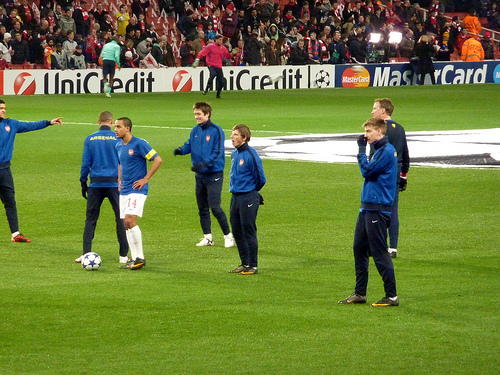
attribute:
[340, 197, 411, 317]
pants — blue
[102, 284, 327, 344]
lawn — pictured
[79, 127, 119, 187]
jacket — blue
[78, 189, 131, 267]
pants — black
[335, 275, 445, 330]
shoes — red 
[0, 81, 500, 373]
field — green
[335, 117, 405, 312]
player — soccer player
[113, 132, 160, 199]
shirt — blue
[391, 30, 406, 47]
light — on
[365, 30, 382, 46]
light — on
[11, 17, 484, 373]
field — green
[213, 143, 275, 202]
jacket — blue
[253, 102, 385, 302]
people — standing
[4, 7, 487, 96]
people — standing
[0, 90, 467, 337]
people — standing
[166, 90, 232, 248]
player — soccer player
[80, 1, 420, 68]
people — standing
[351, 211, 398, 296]
pants — black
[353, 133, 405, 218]
jacket — blue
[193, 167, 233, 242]
pants — black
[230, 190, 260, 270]
pants — blue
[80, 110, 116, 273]
people — standing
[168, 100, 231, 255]
people — standing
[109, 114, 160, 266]
people — standing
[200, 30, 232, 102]
people — standing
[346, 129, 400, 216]
shirt — blue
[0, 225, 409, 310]
shoes — white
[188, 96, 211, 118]
hair — short